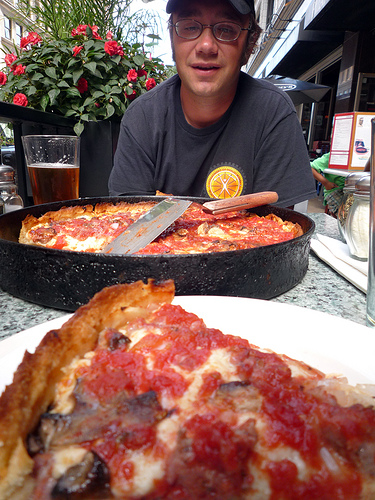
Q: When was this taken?
A: Daytime.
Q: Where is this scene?
A: At a restaurant.